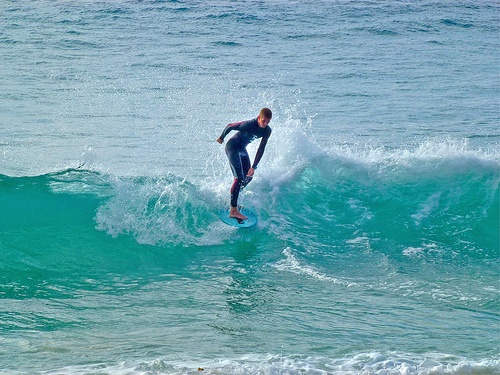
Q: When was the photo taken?
A: Daytime.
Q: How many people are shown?
A: One.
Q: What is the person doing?
A: Surfing.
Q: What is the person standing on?
A: Surfboard.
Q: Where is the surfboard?
A: Water.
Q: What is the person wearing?
A: Wet suit.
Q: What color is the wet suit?
A: Blue.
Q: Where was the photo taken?
A: The ocean.